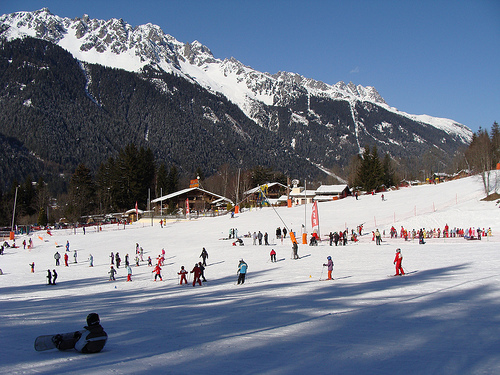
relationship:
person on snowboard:
[393, 248, 405, 276] [390, 271, 417, 276]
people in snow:
[151, 263, 162, 282] [0, 170, 497, 373]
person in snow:
[107, 264, 117, 282] [0, 170, 497, 373]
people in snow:
[236, 258, 249, 285] [0, 170, 497, 373]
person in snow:
[198, 245, 210, 264] [0, 170, 497, 373]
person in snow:
[49, 269, 58, 285] [0, 170, 497, 373]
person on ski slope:
[390, 240, 420, 292] [312, 185, 489, 373]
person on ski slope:
[288, 229, 308, 262] [8, 176, 496, 371]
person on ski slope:
[71, 246, 79, 264] [8, 176, 496, 371]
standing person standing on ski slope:
[415, 226, 426, 246] [8, 176, 496, 371]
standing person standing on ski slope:
[26, 236, 34, 246] [8, 176, 496, 371]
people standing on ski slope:
[323, 255, 335, 279] [8, 176, 496, 371]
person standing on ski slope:
[393, 248, 405, 276] [8, 176, 496, 371]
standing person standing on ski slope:
[290, 236, 301, 259] [8, 176, 496, 371]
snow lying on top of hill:
[2, 6, 263, 114] [0, 0, 497, 222]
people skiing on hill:
[177, 266, 188, 285] [0, 171, 497, 373]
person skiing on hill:
[185, 260, 205, 286] [0, 171, 497, 373]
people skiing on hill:
[236, 258, 249, 285] [0, 171, 497, 373]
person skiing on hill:
[199, 247, 209, 266] [0, 171, 497, 373]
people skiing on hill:
[151, 263, 162, 282] [0, 171, 497, 373]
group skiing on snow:
[22, 223, 493, 286] [0, 170, 497, 373]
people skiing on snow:
[236, 258, 249, 285] [0, 170, 497, 373]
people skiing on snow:
[323, 255, 335, 279] [0, 170, 497, 373]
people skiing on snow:
[177, 266, 188, 285] [0, 170, 497, 373]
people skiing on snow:
[151, 263, 162, 282] [0, 170, 497, 373]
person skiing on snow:
[106, 263, 118, 281] [0, 170, 497, 373]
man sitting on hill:
[52, 311, 108, 355] [0, 171, 500, 223]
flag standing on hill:
[306, 195, 326, 240] [0, 171, 497, 373]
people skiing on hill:
[52, 269, 57, 285] [0, 171, 497, 373]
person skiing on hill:
[47, 269, 52, 285] [0, 171, 497, 373]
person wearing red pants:
[393, 248, 405, 276] [328, 270, 332, 279]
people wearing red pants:
[323, 255, 335, 279] [395, 263, 403, 274]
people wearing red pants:
[236, 258, 249, 285] [193, 276, 200, 286]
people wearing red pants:
[190, 263, 202, 286] [179, 275, 187, 285]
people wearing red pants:
[151, 263, 162, 282] [127, 274, 131, 281]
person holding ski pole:
[393, 248, 405, 276] [319, 265, 324, 280]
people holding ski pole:
[323, 255, 335, 279] [266, 256, 271, 263]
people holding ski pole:
[236, 258, 249, 285] [233, 272, 238, 284]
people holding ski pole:
[190, 263, 202, 286] [188, 272, 192, 285]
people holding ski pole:
[151, 263, 162, 282] [177, 274, 181, 285]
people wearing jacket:
[236, 258, 249, 285] [237, 265, 249, 275]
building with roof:
[313, 181, 349, 202] [314, 183, 350, 193]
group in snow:
[20, 220, 491, 290] [6, 113, 498, 365]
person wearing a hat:
[393, 248, 405, 276] [390, 241, 416, 257]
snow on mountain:
[2, 6, 296, 101] [4, 7, 484, 214]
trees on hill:
[465, 122, 496, 174] [311, 105, 498, 256]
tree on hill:
[364, 143, 385, 193] [311, 105, 498, 256]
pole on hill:
[11, 184, 19, 235] [0, 171, 497, 373]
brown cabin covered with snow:
[151, 187, 236, 216] [151, 181, 226, 197]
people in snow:
[195, 214, 477, 311] [0, 170, 497, 373]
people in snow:
[416, 232, 423, 242] [0, 170, 497, 373]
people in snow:
[373, 227, 383, 245] [0, 170, 497, 373]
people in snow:
[349, 231, 358, 244] [0, 170, 497, 373]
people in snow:
[331, 230, 341, 247] [0, 170, 497, 373]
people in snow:
[326, 230, 334, 245] [0, 170, 497, 373]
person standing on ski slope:
[265, 247, 276, 265] [8, 176, 496, 371]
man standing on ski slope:
[52, 313, 108, 353] [8, 176, 496, 371]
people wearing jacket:
[236, 258, 249, 285] [237, 261, 246, 275]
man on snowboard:
[52, 313, 108, 353] [30, 334, 72, 359]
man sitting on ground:
[52, 313, 108, 353] [0, 165, 498, 372]